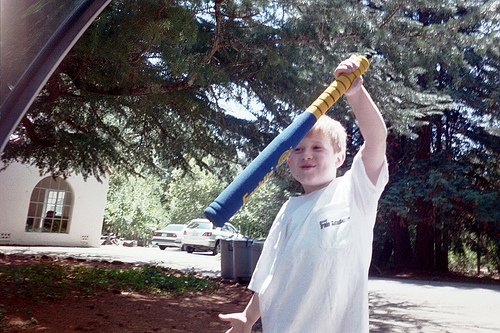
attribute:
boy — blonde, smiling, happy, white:
[271, 85, 374, 330]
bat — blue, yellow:
[243, 162, 270, 191]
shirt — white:
[320, 226, 380, 303]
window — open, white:
[30, 181, 72, 237]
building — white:
[15, 174, 96, 249]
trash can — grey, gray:
[218, 237, 240, 276]